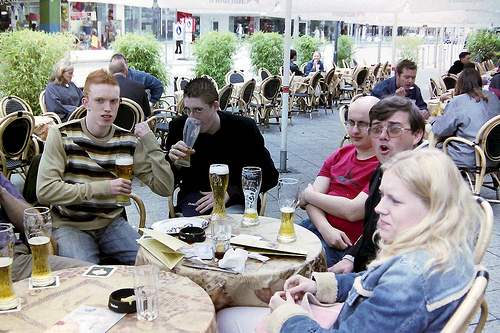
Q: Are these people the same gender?
A: No, they are both male and female.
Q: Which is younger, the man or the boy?
A: The boy is younger than the man.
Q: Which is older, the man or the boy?
A: The man is older than the boy.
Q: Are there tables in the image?
A: Yes, there is a table.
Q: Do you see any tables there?
A: Yes, there is a table.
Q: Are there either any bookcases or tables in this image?
A: Yes, there is a table.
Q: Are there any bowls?
A: No, there are no bowls.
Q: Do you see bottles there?
A: No, there are no bottles.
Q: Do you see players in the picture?
A: No, there are no players.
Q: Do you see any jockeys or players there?
A: No, there are no players or jockeys.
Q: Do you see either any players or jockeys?
A: No, there are no players or jockeys.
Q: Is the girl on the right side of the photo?
A: Yes, the girl is on the right of the image.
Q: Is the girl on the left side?
A: No, the girl is on the right of the image.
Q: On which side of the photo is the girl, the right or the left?
A: The girl is on the right of the image.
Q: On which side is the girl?
A: The girl is on the right of the image.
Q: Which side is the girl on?
A: The girl is on the right of the image.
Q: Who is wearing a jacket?
A: The girl is wearing a jacket.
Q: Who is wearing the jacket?
A: The girl is wearing a jacket.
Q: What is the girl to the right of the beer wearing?
A: The girl is wearing a jacket.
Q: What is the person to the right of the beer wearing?
A: The girl is wearing a jacket.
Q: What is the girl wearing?
A: The girl is wearing a jacket.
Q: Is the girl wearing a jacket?
A: Yes, the girl is wearing a jacket.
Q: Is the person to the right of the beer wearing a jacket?
A: Yes, the girl is wearing a jacket.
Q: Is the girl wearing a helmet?
A: No, the girl is wearing a jacket.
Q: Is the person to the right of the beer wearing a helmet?
A: No, the girl is wearing a jacket.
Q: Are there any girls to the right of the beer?
A: Yes, there is a girl to the right of the beer.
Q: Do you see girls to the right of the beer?
A: Yes, there is a girl to the right of the beer.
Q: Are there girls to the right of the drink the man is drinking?
A: Yes, there is a girl to the right of the beer.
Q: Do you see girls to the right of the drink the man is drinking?
A: Yes, there is a girl to the right of the beer.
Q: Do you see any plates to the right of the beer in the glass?
A: No, there is a girl to the right of the beer.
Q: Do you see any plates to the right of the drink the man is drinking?
A: No, there is a girl to the right of the beer.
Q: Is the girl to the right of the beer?
A: Yes, the girl is to the right of the beer.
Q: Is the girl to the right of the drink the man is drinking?
A: Yes, the girl is to the right of the beer.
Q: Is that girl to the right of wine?
A: No, the girl is to the right of the beer.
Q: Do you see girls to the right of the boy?
A: Yes, there is a girl to the right of the boy.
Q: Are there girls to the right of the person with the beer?
A: Yes, there is a girl to the right of the boy.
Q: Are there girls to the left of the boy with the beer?
A: No, the girl is to the right of the boy.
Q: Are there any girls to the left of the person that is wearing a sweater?
A: No, the girl is to the right of the boy.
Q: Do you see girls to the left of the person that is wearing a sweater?
A: No, the girl is to the right of the boy.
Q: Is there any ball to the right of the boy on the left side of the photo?
A: No, there is a girl to the right of the boy.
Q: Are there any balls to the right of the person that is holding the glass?
A: No, there is a girl to the right of the boy.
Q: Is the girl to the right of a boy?
A: Yes, the girl is to the right of a boy.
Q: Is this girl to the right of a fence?
A: No, the girl is to the right of a boy.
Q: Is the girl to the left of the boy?
A: No, the girl is to the right of the boy.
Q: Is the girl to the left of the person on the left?
A: No, the girl is to the right of the boy.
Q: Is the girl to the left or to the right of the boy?
A: The girl is to the right of the boy.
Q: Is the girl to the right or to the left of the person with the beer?
A: The girl is to the right of the boy.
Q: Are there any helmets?
A: No, there are no helmets.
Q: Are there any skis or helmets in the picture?
A: No, there are no helmets or skis.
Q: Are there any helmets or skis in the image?
A: No, there are no helmets or skis.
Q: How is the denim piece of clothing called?
A: The clothing item is a jacket.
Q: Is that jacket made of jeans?
A: Yes, the jacket is made of jeans.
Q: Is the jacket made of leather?
A: No, the jacket is made of jeans.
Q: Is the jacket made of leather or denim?
A: The jacket is made of denim.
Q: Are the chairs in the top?
A: Yes, the chairs are in the top of the image.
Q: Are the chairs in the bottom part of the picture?
A: No, the chairs are in the top of the image.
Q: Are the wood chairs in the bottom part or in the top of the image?
A: The chairs are in the top of the image.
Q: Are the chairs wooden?
A: Yes, the chairs are wooden.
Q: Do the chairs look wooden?
A: Yes, the chairs are wooden.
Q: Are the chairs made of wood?
A: Yes, the chairs are made of wood.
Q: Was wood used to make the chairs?
A: Yes, the chairs are made of wood.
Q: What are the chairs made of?
A: The chairs are made of wood.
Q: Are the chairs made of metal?
A: No, the chairs are made of wood.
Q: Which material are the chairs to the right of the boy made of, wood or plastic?
A: The chairs are made of wood.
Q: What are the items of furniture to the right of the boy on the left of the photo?
A: The pieces of furniture are chairs.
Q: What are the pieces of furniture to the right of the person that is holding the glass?
A: The pieces of furniture are chairs.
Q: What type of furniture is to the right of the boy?
A: The pieces of furniture are chairs.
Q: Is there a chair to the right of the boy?
A: Yes, there are chairs to the right of the boy.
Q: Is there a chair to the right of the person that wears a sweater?
A: Yes, there are chairs to the right of the boy.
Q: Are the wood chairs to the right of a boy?
A: Yes, the chairs are to the right of a boy.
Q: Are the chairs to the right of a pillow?
A: No, the chairs are to the right of a boy.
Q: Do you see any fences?
A: No, there are no fences.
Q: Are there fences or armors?
A: No, there are no fences or armors.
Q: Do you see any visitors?
A: No, there are no visitors.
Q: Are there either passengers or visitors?
A: No, there are no visitors or passengers.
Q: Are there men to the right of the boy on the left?
A: Yes, there is a man to the right of the boy.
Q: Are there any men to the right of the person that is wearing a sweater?
A: Yes, there is a man to the right of the boy.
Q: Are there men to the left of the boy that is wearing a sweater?
A: No, the man is to the right of the boy.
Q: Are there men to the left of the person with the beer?
A: No, the man is to the right of the boy.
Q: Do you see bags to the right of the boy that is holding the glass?
A: No, there is a man to the right of the boy.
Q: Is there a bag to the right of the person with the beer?
A: No, there is a man to the right of the boy.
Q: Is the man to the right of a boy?
A: Yes, the man is to the right of a boy.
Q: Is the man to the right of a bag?
A: No, the man is to the right of a boy.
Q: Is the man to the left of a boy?
A: No, the man is to the right of a boy.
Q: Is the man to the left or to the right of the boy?
A: The man is to the right of the boy.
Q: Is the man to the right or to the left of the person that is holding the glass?
A: The man is to the right of the boy.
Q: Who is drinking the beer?
A: The man is drinking the beer.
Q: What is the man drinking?
A: The man is drinking beer.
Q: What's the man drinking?
A: The man is drinking beer.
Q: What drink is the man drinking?
A: The man is drinking beer.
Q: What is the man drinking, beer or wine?
A: The man is drinking beer.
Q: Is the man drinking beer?
A: Yes, the man is drinking beer.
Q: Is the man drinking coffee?
A: No, the man is drinking beer.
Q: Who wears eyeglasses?
A: The man wears eyeglasses.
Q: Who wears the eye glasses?
A: The man wears eyeglasses.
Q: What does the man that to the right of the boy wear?
A: The man wears eyeglasses.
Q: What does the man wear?
A: The man wears eyeglasses.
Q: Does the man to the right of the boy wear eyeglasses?
A: Yes, the man wears eyeglasses.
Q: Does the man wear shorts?
A: No, the man wears eyeglasses.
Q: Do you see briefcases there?
A: No, there are no briefcases.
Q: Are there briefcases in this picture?
A: No, there are no briefcases.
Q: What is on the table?
A: The glass is on the table.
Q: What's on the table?
A: The glass is on the table.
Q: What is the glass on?
A: The glass is on the table.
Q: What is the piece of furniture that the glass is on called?
A: The piece of furniture is a table.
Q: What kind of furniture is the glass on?
A: The glass is on the table.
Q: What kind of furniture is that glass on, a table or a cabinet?
A: The glass is on a table.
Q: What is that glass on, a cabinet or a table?
A: The glass is on a table.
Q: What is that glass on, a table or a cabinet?
A: The glass is on a table.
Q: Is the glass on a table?
A: Yes, the glass is on a table.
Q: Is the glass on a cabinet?
A: No, the glass is on a table.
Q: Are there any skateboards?
A: No, there are no skateboards.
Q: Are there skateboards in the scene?
A: No, there are no skateboards.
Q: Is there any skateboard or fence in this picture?
A: No, there are no skateboards or fences.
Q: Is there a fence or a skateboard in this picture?
A: No, there are no skateboards or fences.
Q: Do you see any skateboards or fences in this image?
A: No, there are no skateboards or fences.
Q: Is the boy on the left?
A: Yes, the boy is on the left of the image.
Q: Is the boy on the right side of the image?
A: No, the boy is on the left of the image.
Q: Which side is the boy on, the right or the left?
A: The boy is on the left of the image.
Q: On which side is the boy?
A: The boy is on the left of the image.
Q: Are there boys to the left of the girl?
A: Yes, there is a boy to the left of the girl.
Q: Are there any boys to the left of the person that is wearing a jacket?
A: Yes, there is a boy to the left of the girl.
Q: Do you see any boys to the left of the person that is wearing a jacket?
A: Yes, there is a boy to the left of the girl.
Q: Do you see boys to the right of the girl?
A: No, the boy is to the left of the girl.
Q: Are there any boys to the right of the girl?
A: No, the boy is to the left of the girl.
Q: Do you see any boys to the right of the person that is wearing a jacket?
A: No, the boy is to the left of the girl.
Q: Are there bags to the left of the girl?
A: No, there is a boy to the left of the girl.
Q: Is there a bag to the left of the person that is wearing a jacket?
A: No, there is a boy to the left of the girl.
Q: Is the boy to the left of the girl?
A: Yes, the boy is to the left of the girl.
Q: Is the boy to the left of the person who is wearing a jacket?
A: Yes, the boy is to the left of the girl.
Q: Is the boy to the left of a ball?
A: No, the boy is to the left of the girl.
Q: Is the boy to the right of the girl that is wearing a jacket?
A: No, the boy is to the left of the girl.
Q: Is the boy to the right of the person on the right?
A: No, the boy is to the left of the girl.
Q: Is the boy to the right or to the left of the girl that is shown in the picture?
A: The boy is to the left of the girl.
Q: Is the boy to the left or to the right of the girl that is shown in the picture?
A: The boy is to the left of the girl.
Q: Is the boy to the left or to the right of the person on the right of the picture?
A: The boy is to the left of the girl.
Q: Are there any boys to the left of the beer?
A: Yes, there is a boy to the left of the beer.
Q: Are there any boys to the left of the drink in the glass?
A: Yes, there is a boy to the left of the beer.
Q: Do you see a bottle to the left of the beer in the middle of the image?
A: No, there is a boy to the left of the beer.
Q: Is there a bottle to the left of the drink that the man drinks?
A: No, there is a boy to the left of the beer.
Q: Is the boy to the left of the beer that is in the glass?
A: Yes, the boy is to the left of the beer.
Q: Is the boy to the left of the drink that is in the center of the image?
A: Yes, the boy is to the left of the beer.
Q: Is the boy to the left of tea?
A: No, the boy is to the left of the beer.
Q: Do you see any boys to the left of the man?
A: Yes, there is a boy to the left of the man.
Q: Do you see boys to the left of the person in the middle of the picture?
A: Yes, there is a boy to the left of the man.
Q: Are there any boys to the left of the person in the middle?
A: Yes, there is a boy to the left of the man.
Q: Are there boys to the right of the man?
A: No, the boy is to the left of the man.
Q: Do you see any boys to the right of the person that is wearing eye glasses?
A: No, the boy is to the left of the man.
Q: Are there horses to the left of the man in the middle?
A: No, there is a boy to the left of the man.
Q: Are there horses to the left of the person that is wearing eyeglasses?
A: No, there is a boy to the left of the man.